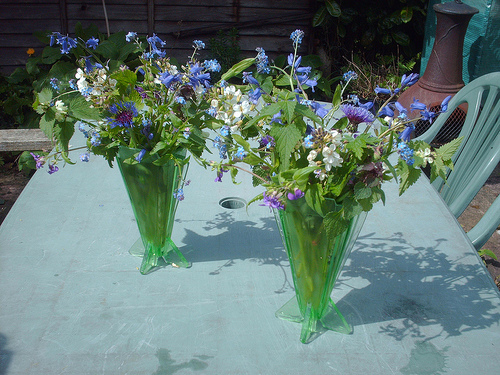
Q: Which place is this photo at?
A: It is at the garden.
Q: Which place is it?
A: It is a garden.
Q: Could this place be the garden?
A: Yes, it is the garden.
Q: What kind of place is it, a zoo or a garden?
A: It is a garden.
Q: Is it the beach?
A: No, it is the garden.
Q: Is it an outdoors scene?
A: Yes, it is outdoors.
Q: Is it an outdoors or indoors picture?
A: It is outdoors.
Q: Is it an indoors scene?
A: No, it is outdoors.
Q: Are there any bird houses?
A: No, there are no bird houses.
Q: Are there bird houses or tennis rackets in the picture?
A: No, there are no bird houses or tennis rackets.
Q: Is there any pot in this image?
A: No, there are no pots.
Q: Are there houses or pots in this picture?
A: No, there are no pots or houses.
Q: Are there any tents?
A: No, there are no tents.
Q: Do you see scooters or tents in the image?
A: No, there are no tents or scooters.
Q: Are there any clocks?
A: No, there are no clocks.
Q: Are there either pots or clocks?
A: No, there are no clocks or pots.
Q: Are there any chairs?
A: Yes, there is a chair.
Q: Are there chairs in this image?
A: Yes, there is a chair.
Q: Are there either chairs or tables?
A: Yes, there is a chair.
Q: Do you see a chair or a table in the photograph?
A: Yes, there is a chair.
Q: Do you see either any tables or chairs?
A: Yes, there is a chair.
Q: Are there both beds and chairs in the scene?
A: No, there is a chair but no beds.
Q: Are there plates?
A: No, there are no plates.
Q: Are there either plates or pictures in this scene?
A: No, there are no plates or pictures.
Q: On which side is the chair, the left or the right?
A: The chair is on the right of the image.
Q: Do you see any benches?
A: Yes, there is a bench.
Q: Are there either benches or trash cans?
A: Yes, there is a bench.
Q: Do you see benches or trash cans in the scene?
A: Yes, there is a bench.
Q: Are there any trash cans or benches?
A: Yes, there is a bench.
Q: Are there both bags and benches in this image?
A: No, there is a bench but no bags.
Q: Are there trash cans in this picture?
A: No, there are no trash cans.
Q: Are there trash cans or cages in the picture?
A: No, there are no trash cans or cages.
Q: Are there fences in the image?
A: Yes, there is a fence.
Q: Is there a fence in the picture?
A: Yes, there is a fence.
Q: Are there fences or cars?
A: Yes, there is a fence.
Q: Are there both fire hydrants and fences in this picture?
A: No, there is a fence but no fire hydrants.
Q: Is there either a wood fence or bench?
A: Yes, there is a wood fence.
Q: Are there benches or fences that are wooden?
A: Yes, the fence is wooden.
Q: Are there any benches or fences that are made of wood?
A: Yes, the fence is made of wood.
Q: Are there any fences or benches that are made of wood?
A: Yes, the fence is made of wood.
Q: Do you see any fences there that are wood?
A: Yes, there is a wood fence.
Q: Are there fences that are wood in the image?
A: Yes, there is a wood fence.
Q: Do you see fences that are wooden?
A: Yes, there is a fence that is wooden.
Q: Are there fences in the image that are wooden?
A: Yes, there is a fence that is wooden.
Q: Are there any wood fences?
A: Yes, there is a fence that is made of wood.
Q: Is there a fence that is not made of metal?
A: Yes, there is a fence that is made of wood.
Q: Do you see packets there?
A: No, there are no packets.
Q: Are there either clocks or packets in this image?
A: No, there are no packets or clocks.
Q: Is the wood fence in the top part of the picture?
A: Yes, the fence is in the top of the image.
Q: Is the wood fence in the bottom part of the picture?
A: No, the fence is in the top of the image.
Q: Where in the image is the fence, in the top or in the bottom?
A: The fence is in the top of the image.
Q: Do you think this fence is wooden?
A: Yes, the fence is wooden.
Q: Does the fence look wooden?
A: Yes, the fence is wooden.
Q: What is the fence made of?
A: The fence is made of wood.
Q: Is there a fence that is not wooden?
A: No, there is a fence but it is wooden.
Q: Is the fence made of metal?
A: No, the fence is made of wood.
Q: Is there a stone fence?
A: No, there is a fence but it is made of wood.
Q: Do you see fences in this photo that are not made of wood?
A: No, there is a fence but it is made of wood.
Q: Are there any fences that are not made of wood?
A: No, there is a fence but it is made of wood.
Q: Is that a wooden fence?
A: Yes, that is a wooden fence.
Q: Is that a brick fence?
A: No, that is a wooden fence.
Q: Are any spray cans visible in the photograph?
A: No, there are no spray cans.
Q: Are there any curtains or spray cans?
A: No, there are no spray cans or curtains.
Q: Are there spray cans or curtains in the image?
A: No, there are no spray cans or curtains.